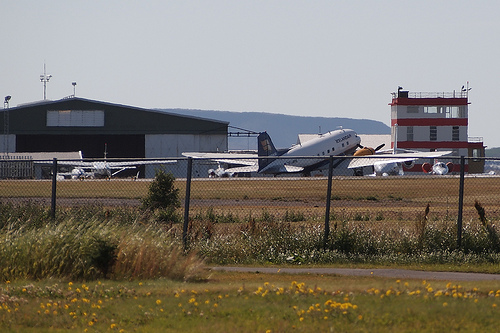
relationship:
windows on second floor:
[402, 128, 466, 138] [389, 126, 469, 145]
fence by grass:
[3, 154, 495, 251] [2, 220, 495, 332]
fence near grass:
[3, 154, 495, 251] [2, 220, 495, 332]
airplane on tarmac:
[184, 126, 450, 175] [14, 172, 493, 179]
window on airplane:
[337, 140, 348, 152] [184, 126, 450, 175]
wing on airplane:
[332, 146, 459, 169] [184, 126, 450, 175]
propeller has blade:
[352, 139, 394, 155] [374, 144, 383, 152]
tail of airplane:
[220, 130, 310, 176] [184, 126, 450, 175]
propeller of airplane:
[353, 143, 386, 156] [184, 126, 450, 175]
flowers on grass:
[235, 272, 332, 301] [2, 220, 495, 332]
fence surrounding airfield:
[3, 154, 495, 251] [4, 80, 499, 208]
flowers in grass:
[235, 272, 332, 301] [2, 220, 495, 332]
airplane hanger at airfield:
[3, 94, 240, 179] [4, 80, 499, 208]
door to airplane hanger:
[142, 134, 202, 174] [3, 94, 240, 179]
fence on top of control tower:
[388, 90, 474, 101] [387, 82, 477, 175]